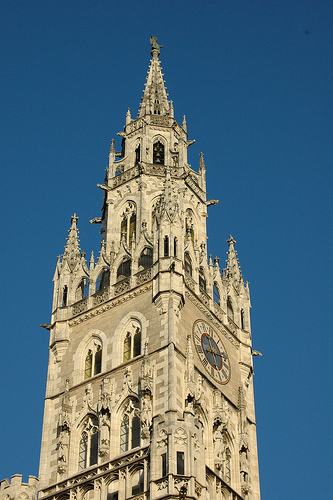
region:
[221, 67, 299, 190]
the blue sky is clear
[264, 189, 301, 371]
the blue sky is clear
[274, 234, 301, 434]
the blue sky is clear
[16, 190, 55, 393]
the blue sky is clear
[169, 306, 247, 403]
the clock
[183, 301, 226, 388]
the clock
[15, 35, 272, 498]
The clock tower of a cathedral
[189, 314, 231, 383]
The face of the clock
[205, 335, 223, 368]
The arms of the clock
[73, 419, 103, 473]
Windows in the clock tower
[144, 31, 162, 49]
A statue at the top of the tower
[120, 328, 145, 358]
Two windows in the tower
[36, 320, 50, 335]
A gargoyle carved in the building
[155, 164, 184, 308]
A roofed part of the tower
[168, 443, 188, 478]
A small window in the tower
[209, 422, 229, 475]
A religious statue under the clock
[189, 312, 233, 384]
Round clock tower.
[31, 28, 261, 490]
The entire tower is made of stone.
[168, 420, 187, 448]
Corner of the tower with small sculpture.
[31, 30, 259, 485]
The tower was built in Gothic style.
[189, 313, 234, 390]
Clock with Roman numbers.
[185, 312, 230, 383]
The center of the clock is blue.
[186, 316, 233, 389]
Clock with golden handles.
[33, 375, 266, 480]
Sculpted statues between the windows.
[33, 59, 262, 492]
The tower has a light tan stone color.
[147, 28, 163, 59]
Tip of the tower with small statue.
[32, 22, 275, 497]
the tower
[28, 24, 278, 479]
the tower is gothic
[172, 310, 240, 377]
the clock on the tower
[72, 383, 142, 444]
windows on the tower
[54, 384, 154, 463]
the windows are arched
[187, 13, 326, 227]
the sky is blue and clear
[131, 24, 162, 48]
the statuette on the tower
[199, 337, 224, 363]
the hands on the clock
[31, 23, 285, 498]
the tower is mason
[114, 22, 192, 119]
the roof of the tower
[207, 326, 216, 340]
roman numeral on clock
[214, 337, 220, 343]
roman numeral on clock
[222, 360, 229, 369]
roman numeral on clock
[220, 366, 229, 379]
roman numeral on clock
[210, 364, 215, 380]
roman numeral on clock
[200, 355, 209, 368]
roman numeral on clock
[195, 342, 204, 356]
roman numeral on clock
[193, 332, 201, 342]
roman numeral on clock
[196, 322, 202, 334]
roman numeral on clock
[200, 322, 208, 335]
roman numeral on clock